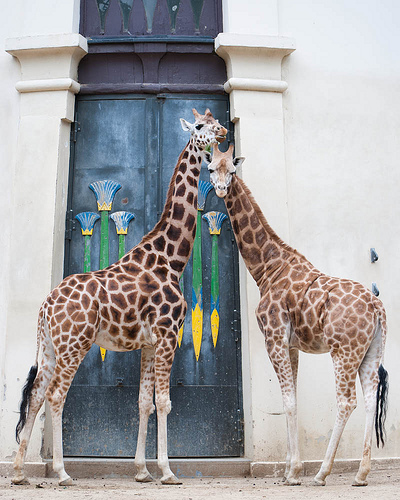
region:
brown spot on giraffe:
[188, 151, 197, 168]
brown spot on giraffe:
[50, 286, 59, 301]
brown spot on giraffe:
[55, 295, 67, 301]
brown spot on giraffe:
[51, 300, 65, 314]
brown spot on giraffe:
[66, 301, 82, 315]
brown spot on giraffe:
[52, 311, 66, 322]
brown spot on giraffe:
[59, 317, 72, 333]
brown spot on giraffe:
[61, 332, 70, 343]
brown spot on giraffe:
[259, 310, 267, 326]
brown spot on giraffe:
[293, 324, 314, 344]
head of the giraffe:
[176, 103, 220, 144]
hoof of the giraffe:
[354, 473, 378, 484]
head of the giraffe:
[157, 470, 187, 485]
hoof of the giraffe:
[135, 466, 155, 484]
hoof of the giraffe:
[52, 472, 80, 489]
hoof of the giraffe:
[3, 473, 32, 490]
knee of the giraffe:
[148, 392, 182, 418]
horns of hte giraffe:
[185, 108, 217, 122]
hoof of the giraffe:
[161, 475, 179, 485]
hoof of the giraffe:
[132, 474, 154, 484]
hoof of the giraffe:
[44, 470, 78, 486]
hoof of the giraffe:
[10, 477, 34, 487]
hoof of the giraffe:
[283, 476, 302, 482]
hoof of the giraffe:
[304, 472, 331, 482]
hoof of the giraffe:
[349, 471, 375, 485]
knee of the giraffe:
[269, 400, 315, 420]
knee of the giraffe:
[159, 404, 195, 416]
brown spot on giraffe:
[228, 196, 243, 218]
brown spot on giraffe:
[241, 229, 256, 246]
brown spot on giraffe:
[255, 226, 267, 248]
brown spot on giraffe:
[263, 257, 283, 276]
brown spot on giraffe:
[166, 223, 184, 240]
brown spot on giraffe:
[175, 236, 191, 258]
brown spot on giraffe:
[166, 242, 176, 258]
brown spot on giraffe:
[132, 248, 145, 264]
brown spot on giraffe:
[142, 252, 156, 269]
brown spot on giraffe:
[153, 265, 167, 283]